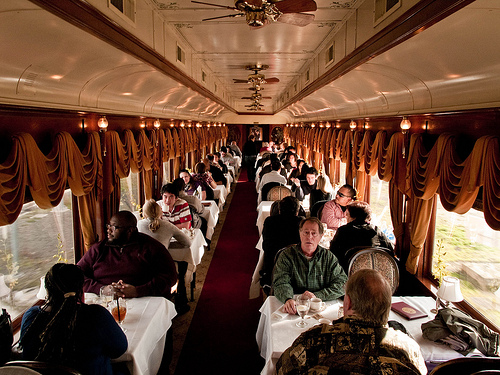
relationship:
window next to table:
[2, 185, 76, 331] [255, 293, 493, 374]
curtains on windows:
[284, 125, 499, 274] [282, 137, 499, 330]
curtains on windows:
[0, 127, 227, 252] [0, 138, 227, 322]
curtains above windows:
[284, 125, 499, 274] [367, 180, 499, 329]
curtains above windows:
[0, 127, 227, 252] [3, 139, 226, 346]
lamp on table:
[431, 273, 466, 316] [255, 293, 493, 374]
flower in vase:
[427, 228, 461, 289] [420, 268, 462, 318]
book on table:
[393, 295, 429, 326] [255, 293, 493, 374]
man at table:
[267, 216, 350, 310] [255, 293, 493, 374]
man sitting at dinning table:
[280, 266, 415, 373] [7, 286, 175, 371]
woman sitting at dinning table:
[18, 263, 127, 373] [7, 294, 179, 374]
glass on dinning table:
[108, 290, 127, 334] [7, 294, 179, 374]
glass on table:
[290, 290, 310, 330] [255, 293, 493, 374]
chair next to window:
[333, 243, 425, 295] [427, 192, 497, 333]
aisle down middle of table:
[171, 149, 256, 374] [255, 293, 493, 374]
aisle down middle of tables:
[171, 149, 256, 374] [2, 144, 243, 374]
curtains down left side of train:
[0, 127, 227, 252] [7, 7, 496, 372]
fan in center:
[205, 0, 320, 34] [151, 3, 348, 114]